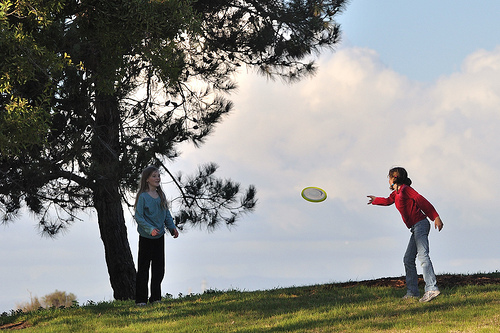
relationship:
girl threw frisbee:
[366, 166, 446, 304] [300, 187, 327, 203]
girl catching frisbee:
[134, 166, 180, 304] [300, 187, 327, 203]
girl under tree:
[134, 166, 180, 304] [1, 0, 350, 300]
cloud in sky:
[168, 0, 500, 222] [1, 0, 499, 313]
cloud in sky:
[403, 46, 500, 222] [1, 0, 499, 313]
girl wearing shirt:
[134, 166, 180, 304] [134, 190, 176, 237]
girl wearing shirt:
[366, 166, 446, 304] [372, 184, 440, 228]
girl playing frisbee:
[366, 166, 446, 304] [300, 187, 327, 203]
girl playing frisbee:
[134, 166, 180, 304] [300, 187, 327, 203]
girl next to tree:
[134, 166, 180, 304] [1, 0, 350, 300]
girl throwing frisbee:
[366, 166, 446, 304] [300, 187, 327, 203]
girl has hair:
[366, 166, 446, 304] [390, 166, 412, 187]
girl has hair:
[134, 166, 180, 304] [134, 166, 169, 210]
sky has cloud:
[1, 0, 499, 313] [168, 0, 500, 222]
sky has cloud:
[1, 0, 499, 313] [403, 46, 500, 222]